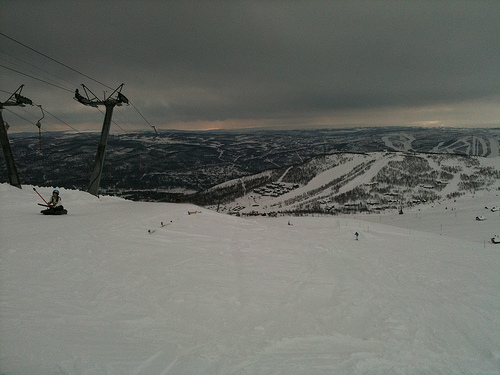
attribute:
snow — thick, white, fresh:
[2, 179, 492, 371]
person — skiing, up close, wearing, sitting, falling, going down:
[28, 188, 78, 220]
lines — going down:
[1, 30, 153, 153]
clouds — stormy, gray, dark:
[2, 3, 486, 137]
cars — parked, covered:
[258, 178, 297, 198]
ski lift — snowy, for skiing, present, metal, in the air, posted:
[4, 85, 45, 136]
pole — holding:
[91, 101, 109, 212]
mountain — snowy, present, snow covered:
[5, 175, 500, 370]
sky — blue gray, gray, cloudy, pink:
[22, 4, 486, 145]